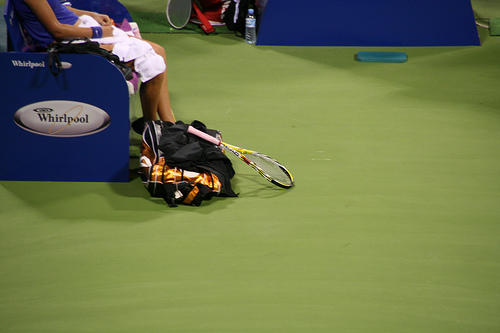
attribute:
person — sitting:
[25, 1, 175, 176]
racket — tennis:
[198, 130, 280, 183]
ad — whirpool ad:
[10, 100, 111, 138]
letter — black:
[29, 95, 116, 144]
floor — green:
[296, 102, 485, 289]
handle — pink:
[186, 117, 233, 151]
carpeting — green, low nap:
[177, 61, 489, 331]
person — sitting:
[6, 0, 197, 140]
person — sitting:
[1, 13, 148, 80]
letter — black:
[37, 110, 47, 124]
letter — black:
[67, 114, 72, 126]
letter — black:
[84, 112, 90, 125]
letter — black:
[70, 114, 80, 124]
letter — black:
[77, 115, 85, 123]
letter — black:
[82, 110, 91, 123]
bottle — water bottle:
[243, 4, 260, 46]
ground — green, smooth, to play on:
[327, 72, 487, 302]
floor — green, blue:
[1, 1, 497, 331]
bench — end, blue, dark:
[1, 1, 131, 181]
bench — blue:
[2, 18, 149, 195]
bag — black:
[159, 119, 217, 168]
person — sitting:
[62, 20, 147, 115]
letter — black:
[37, 111, 48, 121]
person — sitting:
[13, 4, 201, 150]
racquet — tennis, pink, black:
[185, 120, 305, 194]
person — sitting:
[7, 0, 176, 131]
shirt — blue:
[7, 0, 84, 43]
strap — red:
[192, 10, 220, 41]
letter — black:
[46, 111, 55, 122]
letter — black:
[52, 113, 60, 123]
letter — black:
[57, 114, 64, 122]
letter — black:
[62, 111, 67, 123]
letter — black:
[66, 112, 73, 125]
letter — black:
[72, 116, 79, 123]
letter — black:
[79, 116, 85, 122]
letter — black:
[84, 112, 91, 124]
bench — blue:
[0, 45, 134, 190]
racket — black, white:
[180, 124, 301, 193]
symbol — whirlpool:
[11, 96, 111, 138]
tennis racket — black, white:
[187, 121, 297, 190]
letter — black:
[54, 113, 60, 124]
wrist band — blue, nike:
[83, 24, 114, 69]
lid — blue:
[235, 9, 256, 17]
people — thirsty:
[91, 22, 283, 242]